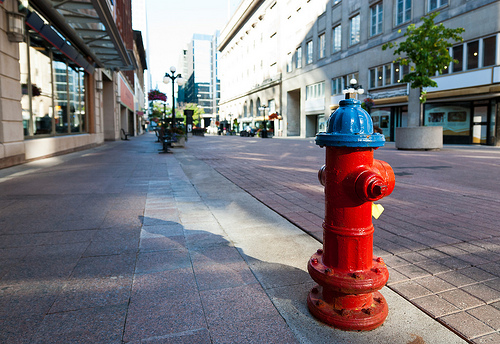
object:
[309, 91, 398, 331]
hydrant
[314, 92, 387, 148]
top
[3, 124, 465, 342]
sidewalk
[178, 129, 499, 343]
floor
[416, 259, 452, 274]
bricks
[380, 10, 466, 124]
tree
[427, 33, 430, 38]
leaves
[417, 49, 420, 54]
leaf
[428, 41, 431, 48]
leaf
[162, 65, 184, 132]
lamp post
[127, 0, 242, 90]
sky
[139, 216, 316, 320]
shadow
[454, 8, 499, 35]
wall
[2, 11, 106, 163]
stores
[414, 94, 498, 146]
stores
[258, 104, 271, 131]
streetlight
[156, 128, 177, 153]
bench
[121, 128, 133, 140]
bench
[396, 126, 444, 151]
planter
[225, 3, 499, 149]
building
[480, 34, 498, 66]
windows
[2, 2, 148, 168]
building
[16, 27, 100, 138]
windows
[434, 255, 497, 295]
pavers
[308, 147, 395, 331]
fire hydrant bottom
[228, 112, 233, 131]
street light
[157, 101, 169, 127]
street light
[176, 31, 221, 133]
building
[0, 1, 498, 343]
city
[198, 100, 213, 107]
windows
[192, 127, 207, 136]
table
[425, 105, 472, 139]
sign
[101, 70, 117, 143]
doorway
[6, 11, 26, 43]
light fixture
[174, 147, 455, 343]
curb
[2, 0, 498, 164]
background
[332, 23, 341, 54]
window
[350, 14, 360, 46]
window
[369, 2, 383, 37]
window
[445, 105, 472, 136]
advertisement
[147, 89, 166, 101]
awning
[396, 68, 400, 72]
lights